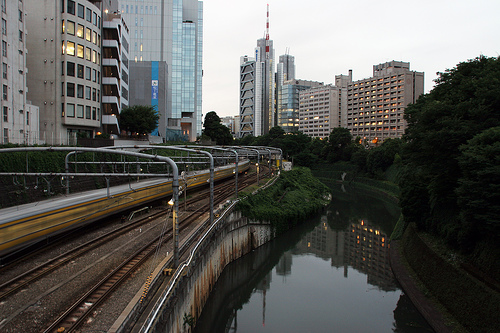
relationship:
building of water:
[305, 83, 403, 165] [316, 144, 398, 230]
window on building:
[63, 100, 76, 119] [0, 0, 107, 154]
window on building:
[77, 102, 84, 122] [29, 1, 104, 143]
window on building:
[61, 23, 70, 31] [63, 14, 120, 144]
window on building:
[67, 51, 110, 121] [63, 14, 120, 144]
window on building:
[57, 2, 112, 38] [63, 14, 120, 144]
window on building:
[61, 20, 73, 34] [29, 1, 104, 143]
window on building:
[74, 24, 86, 40] [58, 40, 90, 107]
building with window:
[29, 1, 104, 143] [61, 0, 103, 118]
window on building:
[184, 20, 191, 30] [156, 4, 206, 136]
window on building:
[189, 51, 194, 57] [156, 4, 206, 136]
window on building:
[179, 65, 183, 70] [156, 4, 206, 136]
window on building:
[171, 78, 178, 84] [156, 4, 206, 136]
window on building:
[179, 85, 188, 98] [156, 4, 206, 136]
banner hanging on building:
[149, 60, 158, 137] [128, 60, 169, 143]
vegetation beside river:
[275, 134, 411, 184] [200, 171, 441, 329]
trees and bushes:
[111, 51, 497, 287] [4, 54, 498, 288]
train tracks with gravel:
[66, 242, 136, 297] [80, 261, 104, 279]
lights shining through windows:
[51, 8, 116, 74] [49, 7, 110, 67]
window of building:
[282, 102, 289, 109] [298, 84, 339, 140]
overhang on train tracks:
[0, 142, 183, 275] [2, 201, 175, 331]